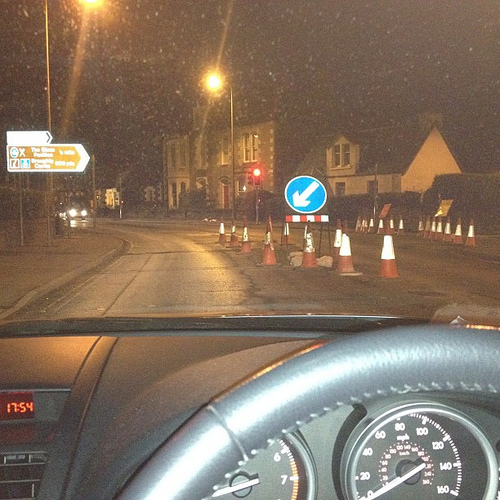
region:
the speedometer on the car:
[346, 400, 496, 497]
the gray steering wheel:
[128, 311, 497, 478]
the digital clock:
[2, 398, 37, 414]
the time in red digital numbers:
[3, 397, 37, 417]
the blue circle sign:
[280, 171, 330, 213]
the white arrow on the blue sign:
[291, 180, 317, 207]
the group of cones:
[210, 206, 394, 281]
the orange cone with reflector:
[379, 226, 404, 283]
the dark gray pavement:
[143, 235, 224, 312]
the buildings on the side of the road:
[152, 81, 489, 231]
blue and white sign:
[275, 162, 337, 216]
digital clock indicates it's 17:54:
[2, 396, 36, 419]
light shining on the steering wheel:
[163, 382, 258, 492]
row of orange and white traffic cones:
[201, 218, 424, 283]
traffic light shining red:
[248, 163, 266, 189]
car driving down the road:
[62, 198, 100, 223]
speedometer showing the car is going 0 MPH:
[338, 409, 481, 499]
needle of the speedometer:
[360, 458, 435, 499]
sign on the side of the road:
[3, 127, 104, 182]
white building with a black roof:
[294, 119, 483, 204]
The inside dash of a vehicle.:
[5, 304, 499, 498]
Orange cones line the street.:
[213, 200, 495, 291]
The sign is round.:
[273, 165, 341, 217]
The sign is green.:
[273, 163, 345, 230]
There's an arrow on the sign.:
[275, 162, 342, 234]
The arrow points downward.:
[275, 167, 351, 234]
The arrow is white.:
[276, 171, 331, 233]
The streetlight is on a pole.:
[196, 68, 241, 227]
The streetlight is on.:
[195, 65, 246, 229]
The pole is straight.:
[195, 64, 246, 230]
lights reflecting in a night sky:
[168, 27, 315, 125]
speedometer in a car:
[350, 415, 483, 499]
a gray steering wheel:
[215, 336, 372, 431]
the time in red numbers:
[3, 393, 50, 425]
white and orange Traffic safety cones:
[334, 230, 404, 289]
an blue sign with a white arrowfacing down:
[273, 165, 338, 217]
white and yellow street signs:
[5, 128, 101, 181]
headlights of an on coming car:
[66, 204, 97, 222]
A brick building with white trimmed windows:
[151, 135, 236, 217]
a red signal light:
[242, 156, 273, 183]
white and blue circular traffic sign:
[279, 162, 340, 229]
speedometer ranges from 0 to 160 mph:
[331, 388, 493, 498]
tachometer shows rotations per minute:
[139, 397, 320, 499]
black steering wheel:
[81, 289, 498, 496]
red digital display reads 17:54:
[3, 375, 53, 432]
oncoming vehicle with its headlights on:
[59, 191, 106, 225]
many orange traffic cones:
[210, 200, 485, 298]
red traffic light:
[236, 156, 282, 228]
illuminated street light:
[185, 40, 271, 262]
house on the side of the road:
[291, 100, 498, 257]